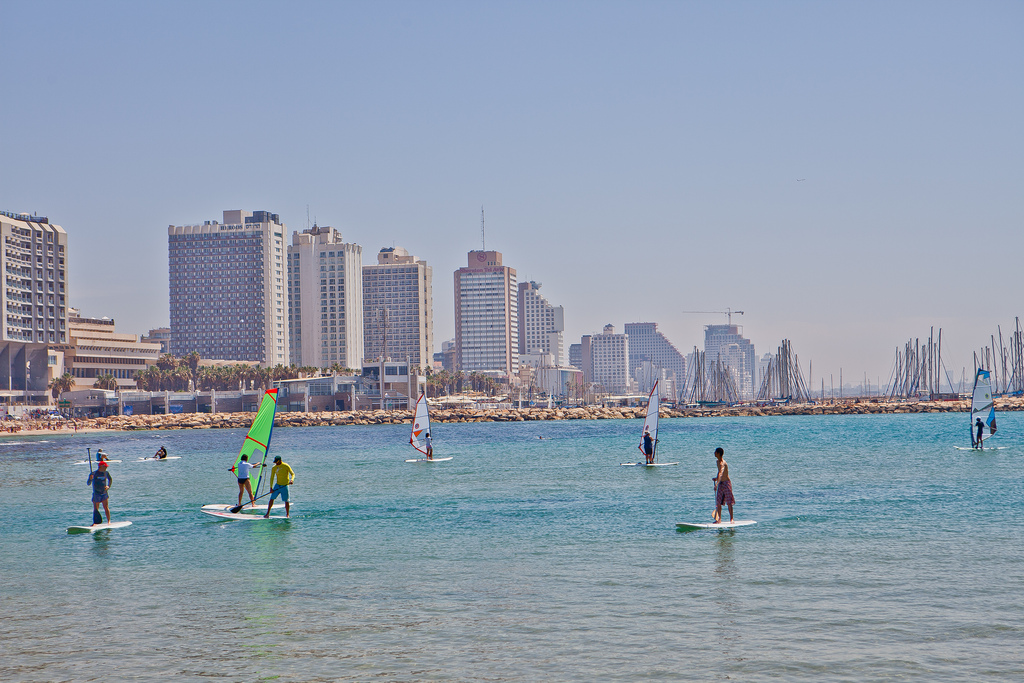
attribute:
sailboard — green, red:
[216, 382, 277, 506]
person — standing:
[691, 439, 750, 520]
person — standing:
[80, 449, 142, 533]